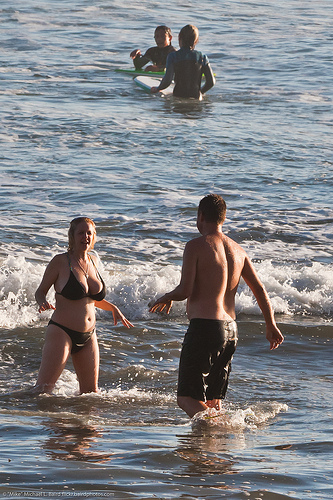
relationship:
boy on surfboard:
[152, 24, 215, 99] [134, 75, 175, 96]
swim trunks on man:
[176, 318, 238, 397] [150, 195, 284, 418]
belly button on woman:
[88, 318, 92, 321] [34, 217, 135, 398]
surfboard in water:
[134, 75, 175, 96] [2, 1, 332, 498]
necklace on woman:
[71, 250, 91, 277] [34, 217, 135, 398]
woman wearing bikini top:
[34, 217, 135, 398] [56, 252, 107, 299]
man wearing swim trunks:
[150, 195, 284, 418] [176, 318, 238, 397]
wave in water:
[5, 249, 332, 328] [2, 1, 332, 498]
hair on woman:
[68, 216, 94, 250] [34, 217, 135, 398]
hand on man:
[266, 327, 283, 348] [150, 195, 284, 418]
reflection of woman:
[40, 415, 123, 465] [34, 217, 135, 398]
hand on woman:
[112, 305, 134, 329] [34, 217, 135, 398]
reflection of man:
[172, 419, 247, 474] [150, 195, 284, 418]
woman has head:
[34, 217, 135, 398] [67, 218, 96, 251]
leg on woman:
[34, 323, 73, 391] [34, 217, 135, 398]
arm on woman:
[35, 255, 59, 304] [34, 217, 135, 398]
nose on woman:
[83, 233, 89, 240] [34, 217, 135, 398]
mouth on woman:
[82, 239, 91, 244] [34, 217, 135, 398]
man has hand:
[150, 195, 284, 418] [147, 293, 172, 314]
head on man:
[195, 194, 227, 234] [150, 195, 284, 418]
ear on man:
[198, 210, 203, 220] [150, 195, 284, 418]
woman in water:
[34, 217, 135, 398] [2, 1, 332, 498]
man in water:
[150, 195, 284, 418] [2, 1, 332, 498]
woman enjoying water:
[34, 217, 135, 398] [2, 1, 332, 498]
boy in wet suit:
[152, 24, 215, 99] [161, 47, 216, 95]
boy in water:
[152, 24, 215, 99] [2, 1, 332, 498]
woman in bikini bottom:
[34, 217, 135, 398] [47, 320, 97, 353]